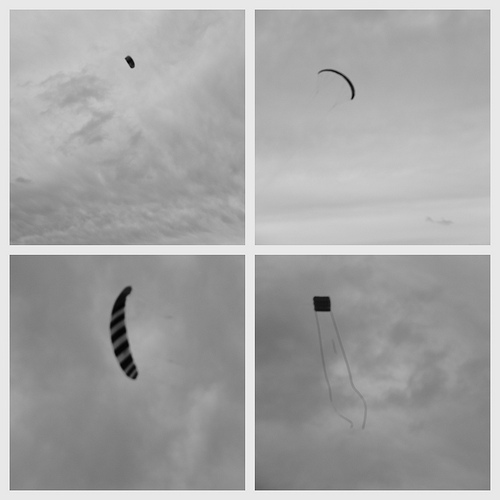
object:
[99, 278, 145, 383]
parasail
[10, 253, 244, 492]
sky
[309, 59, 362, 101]
parasail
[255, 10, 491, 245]
air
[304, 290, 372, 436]
kite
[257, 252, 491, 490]
air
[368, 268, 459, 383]
sky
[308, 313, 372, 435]
tail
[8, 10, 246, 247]
sky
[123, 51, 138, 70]
kite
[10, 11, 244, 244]
clouds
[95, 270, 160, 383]
kite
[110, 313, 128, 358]
stripes